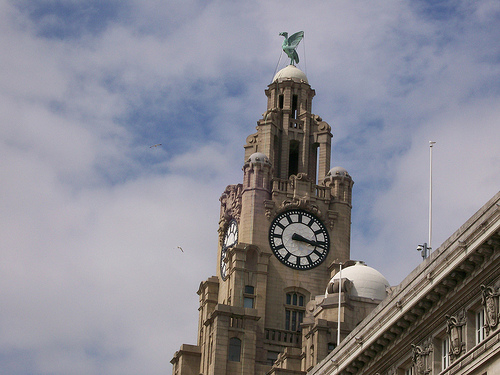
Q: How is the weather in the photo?
A: It is cloudy.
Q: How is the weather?
A: It is cloudy.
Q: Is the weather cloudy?
A: Yes, it is cloudy.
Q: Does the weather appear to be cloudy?
A: Yes, it is cloudy.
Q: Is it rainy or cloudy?
A: It is cloudy.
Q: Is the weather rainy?
A: No, it is cloudy.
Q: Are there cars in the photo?
A: No, there are no cars.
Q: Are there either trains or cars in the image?
A: No, there are no cars or trains.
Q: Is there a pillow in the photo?
A: No, there are no pillows.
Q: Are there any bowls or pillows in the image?
A: No, there are no pillows or bowls.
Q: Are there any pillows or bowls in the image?
A: No, there are no pillows or bowls.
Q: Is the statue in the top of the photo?
A: Yes, the statue is in the top of the image.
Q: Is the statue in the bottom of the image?
A: No, the statue is in the top of the image.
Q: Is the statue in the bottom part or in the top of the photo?
A: The statue is in the top of the image.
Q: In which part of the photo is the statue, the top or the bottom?
A: The statue is in the top of the image.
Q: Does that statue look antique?
A: Yes, the statue is antique.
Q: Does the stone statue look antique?
A: Yes, the statue is antique.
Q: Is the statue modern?
A: No, the statue is antique.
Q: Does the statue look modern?
A: No, the statue is antique.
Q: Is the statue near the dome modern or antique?
A: The statue is antique.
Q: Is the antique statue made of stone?
A: Yes, the statue is made of stone.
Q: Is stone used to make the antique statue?
A: Yes, the statue is made of stone.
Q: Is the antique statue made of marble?
A: No, the statue is made of stone.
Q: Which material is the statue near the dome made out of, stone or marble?
A: The statue is made of stone.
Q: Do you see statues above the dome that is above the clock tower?
A: Yes, there is a statue above the dome.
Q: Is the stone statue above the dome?
A: Yes, the statue is above the dome.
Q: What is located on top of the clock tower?
A: The statue is on top of the clock tower.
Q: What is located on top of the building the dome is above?
A: The statue is on top of the clock tower.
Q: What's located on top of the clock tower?
A: The statue is on top of the clock tower.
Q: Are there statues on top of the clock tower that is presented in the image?
A: Yes, there is a statue on top of the clock tower.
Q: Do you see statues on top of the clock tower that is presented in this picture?
A: Yes, there is a statue on top of the clock tower.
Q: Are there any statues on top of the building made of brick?
A: Yes, there is a statue on top of the clock tower.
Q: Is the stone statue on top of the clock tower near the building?
A: Yes, the statue is on top of the clock tower.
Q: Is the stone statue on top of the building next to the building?
A: Yes, the statue is on top of the clock tower.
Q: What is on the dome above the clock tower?
A: The statue is on the dome.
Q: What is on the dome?
A: The statue is on the dome.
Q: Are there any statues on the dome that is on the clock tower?
A: Yes, there is a statue on the dome.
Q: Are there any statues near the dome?
A: Yes, there is a statue near the dome.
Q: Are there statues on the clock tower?
A: Yes, there is a statue on the clock tower.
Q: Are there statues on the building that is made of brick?
A: Yes, there is a statue on the clock tower.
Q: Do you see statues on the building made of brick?
A: Yes, there is a statue on the clock tower.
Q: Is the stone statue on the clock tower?
A: Yes, the statue is on the clock tower.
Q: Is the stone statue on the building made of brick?
A: Yes, the statue is on the clock tower.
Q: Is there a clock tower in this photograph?
A: Yes, there is a clock tower.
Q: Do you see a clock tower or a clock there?
A: Yes, there is a clock tower.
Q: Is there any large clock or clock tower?
A: Yes, there is a large clock tower.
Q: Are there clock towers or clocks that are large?
A: Yes, the clock tower is large.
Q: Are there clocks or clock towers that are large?
A: Yes, the clock tower is large.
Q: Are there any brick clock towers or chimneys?
A: Yes, there is a brick clock tower.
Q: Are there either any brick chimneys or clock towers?
A: Yes, there is a brick clock tower.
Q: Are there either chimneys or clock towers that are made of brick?
A: Yes, the clock tower is made of brick.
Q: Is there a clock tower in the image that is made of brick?
A: Yes, there is a clock tower that is made of brick.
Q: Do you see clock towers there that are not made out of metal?
A: Yes, there is a clock tower that is made of brick.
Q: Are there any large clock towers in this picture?
A: Yes, there is a large clock tower.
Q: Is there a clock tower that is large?
A: Yes, there is a clock tower that is large.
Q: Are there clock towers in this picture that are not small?
A: Yes, there is a large clock tower.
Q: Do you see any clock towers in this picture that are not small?
A: Yes, there is a large clock tower.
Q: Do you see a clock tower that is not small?
A: Yes, there is a large clock tower.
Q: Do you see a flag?
A: No, there are no flags.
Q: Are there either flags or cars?
A: No, there are no flags or cars.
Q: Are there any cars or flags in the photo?
A: No, there are no flags or cars.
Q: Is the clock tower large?
A: Yes, the clock tower is large.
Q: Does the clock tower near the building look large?
A: Yes, the clock tower is large.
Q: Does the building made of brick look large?
A: Yes, the clock tower is large.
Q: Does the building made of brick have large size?
A: Yes, the clock tower is large.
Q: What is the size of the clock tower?
A: The clock tower is large.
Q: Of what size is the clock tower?
A: The clock tower is large.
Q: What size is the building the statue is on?
A: The clock tower is large.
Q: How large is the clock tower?
A: The clock tower is large.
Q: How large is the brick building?
A: The clock tower is large.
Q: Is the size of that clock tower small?
A: No, the clock tower is large.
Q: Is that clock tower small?
A: No, the clock tower is large.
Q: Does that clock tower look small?
A: No, the clock tower is large.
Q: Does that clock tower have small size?
A: No, the clock tower is large.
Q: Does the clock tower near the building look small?
A: No, the clock tower is large.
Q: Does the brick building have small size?
A: No, the clock tower is large.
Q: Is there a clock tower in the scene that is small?
A: No, there is a clock tower but it is large.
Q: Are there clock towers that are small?
A: No, there is a clock tower but it is large.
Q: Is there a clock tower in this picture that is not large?
A: No, there is a clock tower but it is large.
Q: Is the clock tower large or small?
A: The clock tower is large.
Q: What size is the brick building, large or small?
A: The clock tower is large.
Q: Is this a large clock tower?
A: Yes, this is a large clock tower.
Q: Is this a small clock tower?
A: No, this is a large clock tower.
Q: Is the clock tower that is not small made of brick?
A: Yes, the clock tower is made of brick.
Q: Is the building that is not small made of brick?
A: Yes, the clock tower is made of brick.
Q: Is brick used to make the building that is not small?
A: Yes, the clock tower is made of brick.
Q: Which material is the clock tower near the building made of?
A: The clock tower is made of brick.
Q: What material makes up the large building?
A: The clock tower is made of brick.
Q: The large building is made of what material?
A: The clock tower is made of brick.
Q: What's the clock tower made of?
A: The clock tower is made of brick.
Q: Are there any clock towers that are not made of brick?
A: No, there is a clock tower but it is made of brick.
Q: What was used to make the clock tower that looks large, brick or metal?
A: The clock tower is made of brick.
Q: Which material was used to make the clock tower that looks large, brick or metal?
A: The clock tower is made of brick.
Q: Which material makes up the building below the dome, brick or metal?
A: The clock tower is made of brick.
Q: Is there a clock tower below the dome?
A: Yes, there is a clock tower below the dome.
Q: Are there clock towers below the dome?
A: Yes, there is a clock tower below the dome.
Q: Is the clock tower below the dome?
A: Yes, the clock tower is below the dome.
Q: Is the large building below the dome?
A: Yes, the clock tower is below the dome.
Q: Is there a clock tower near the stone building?
A: Yes, there is a clock tower near the building.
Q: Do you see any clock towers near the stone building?
A: Yes, there is a clock tower near the building.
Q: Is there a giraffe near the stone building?
A: No, there is a clock tower near the building.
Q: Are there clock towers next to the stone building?
A: Yes, there is a clock tower next to the building.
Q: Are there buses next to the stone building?
A: No, there is a clock tower next to the building.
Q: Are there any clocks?
A: Yes, there is a clock.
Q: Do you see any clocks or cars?
A: Yes, there is a clock.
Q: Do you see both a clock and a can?
A: No, there is a clock but no cans.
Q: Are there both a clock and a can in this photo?
A: No, there is a clock but no cans.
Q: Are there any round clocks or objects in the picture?
A: Yes, there is a round clock.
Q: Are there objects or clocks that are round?
A: Yes, the clock is round.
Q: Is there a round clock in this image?
A: Yes, there is a round clock.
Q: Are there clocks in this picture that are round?
A: Yes, there is a clock that is round.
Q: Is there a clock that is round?
A: Yes, there is a clock that is round.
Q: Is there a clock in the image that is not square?
A: Yes, there is a round clock.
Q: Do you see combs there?
A: No, there are no combs.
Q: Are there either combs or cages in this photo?
A: No, there are no combs or cages.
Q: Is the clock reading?
A: Yes, the clock is reading.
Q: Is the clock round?
A: Yes, the clock is round.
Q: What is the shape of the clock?
A: The clock is round.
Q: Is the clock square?
A: No, the clock is round.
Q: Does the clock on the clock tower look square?
A: No, the clock is round.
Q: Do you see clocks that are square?
A: No, there is a clock but it is round.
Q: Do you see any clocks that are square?
A: No, there is a clock but it is round.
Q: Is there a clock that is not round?
A: No, there is a clock but it is round.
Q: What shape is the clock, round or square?
A: The clock is round.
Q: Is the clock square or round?
A: The clock is round.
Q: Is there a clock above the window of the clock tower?
A: Yes, there is a clock above the window.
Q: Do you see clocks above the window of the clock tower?
A: Yes, there is a clock above the window.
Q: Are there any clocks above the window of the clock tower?
A: Yes, there is a clock above the window.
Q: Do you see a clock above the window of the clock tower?
A: Yes, there is a clock above the window.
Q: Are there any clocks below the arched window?
A: No, the clock is above the window.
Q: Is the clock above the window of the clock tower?
A: Yes, the clock is above the window.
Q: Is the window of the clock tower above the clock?
A: No, the clock is above the window.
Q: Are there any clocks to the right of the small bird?
A: Yes, there is a clock to the right of the bird.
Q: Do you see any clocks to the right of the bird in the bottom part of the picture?
A: Yes, there is a clock to the right of the bird.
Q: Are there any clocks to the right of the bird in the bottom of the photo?
A: Yes, there is a clock to the right of the bird.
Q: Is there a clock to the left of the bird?
A: No, the clock is to the right of the bird.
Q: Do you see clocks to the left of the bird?
A: No, the clock is to the right of the bird.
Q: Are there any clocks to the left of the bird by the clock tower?
A: No, the clock is to the right of the bird.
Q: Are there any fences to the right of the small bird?
A: No, there is a clock to the right of the bird.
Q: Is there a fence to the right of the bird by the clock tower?
A: No, there is a clock to the right of the bird.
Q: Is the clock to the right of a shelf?
A: No, the clock is to the right of a bird.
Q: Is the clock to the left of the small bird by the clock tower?
A: No, the clock is to the right of the bird.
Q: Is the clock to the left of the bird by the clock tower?
A: No, the clock is to the right of the bird.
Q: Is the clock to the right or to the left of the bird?
A: The clock is to the right of the bird.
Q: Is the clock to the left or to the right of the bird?
A: The clock is to the right of the bird.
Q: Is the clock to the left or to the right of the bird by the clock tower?
A: The clock is to the right of the bird.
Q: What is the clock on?
A: The clock is on the clock tower.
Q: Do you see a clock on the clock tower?
A: Yes, there is a clock on the clock tower.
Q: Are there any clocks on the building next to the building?
A: Yes, there is a clock on the clock tower.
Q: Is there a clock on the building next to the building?
A: Yes, there is a clock on the clock tower.